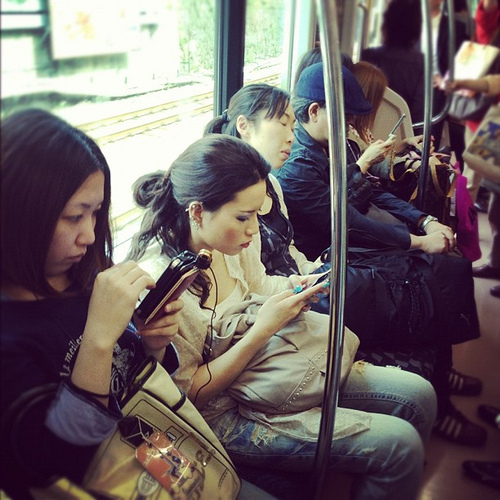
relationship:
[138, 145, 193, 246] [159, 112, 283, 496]
ponytail on woman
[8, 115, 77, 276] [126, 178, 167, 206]
hair in bun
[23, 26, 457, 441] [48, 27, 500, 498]
people on bus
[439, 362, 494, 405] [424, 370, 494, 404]
shoe on foot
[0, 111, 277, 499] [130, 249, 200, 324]
woman looking at phone